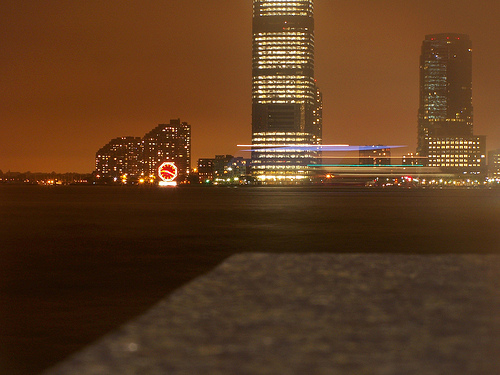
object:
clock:
[157, 162, 179, 182]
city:
[2, 0, 499, 375]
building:
[249, 1, 322, 189]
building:
[417, 32, 487, 174]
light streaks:
[235, 133, 446, 179]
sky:
[0, 0, 499, 174]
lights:
[430, 47, 433, 51]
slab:
[44, 249, 500, 373]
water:
[0, 185, 498, 374]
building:
[143, 118, 194, 184]